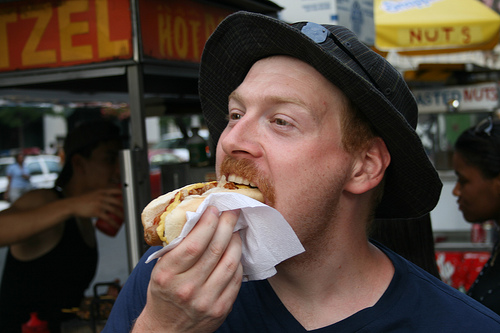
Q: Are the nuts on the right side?
A: Yes, the nuts are on the right of the image.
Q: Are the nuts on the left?
A: No, the nuts are on the right of the image.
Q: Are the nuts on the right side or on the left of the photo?
A: The nuts are on the right of the image.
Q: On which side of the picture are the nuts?
A: The nuts are on the right of the image.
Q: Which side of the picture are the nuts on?
A: The nuts are on the right of the image.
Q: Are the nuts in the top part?
A: Yes, the nuts are in the top of the image.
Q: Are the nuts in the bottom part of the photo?
A: No, the nuts are in the top of the image.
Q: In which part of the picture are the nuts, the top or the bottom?
A: The nuts are in the top of the image.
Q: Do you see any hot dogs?
A: Yes, there is a hot dog.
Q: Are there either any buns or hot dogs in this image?
A: Yes, there is a hot dog.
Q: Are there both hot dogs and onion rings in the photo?
A: No, there is a hot dog but no onion rings.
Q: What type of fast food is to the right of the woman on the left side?
A: The food is a hot dog.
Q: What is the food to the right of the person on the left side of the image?
A: The food is a hot dog.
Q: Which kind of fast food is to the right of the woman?
A: The food is a hot dog.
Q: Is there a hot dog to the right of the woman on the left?
A: Yes, there is a hot dog to the right of the woman.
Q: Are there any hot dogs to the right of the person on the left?
A: Yes, there is a hot dog to the right of the woman.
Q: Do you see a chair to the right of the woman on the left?
A: No, there is a hot dog to the right of the woman.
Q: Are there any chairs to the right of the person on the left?
A: No, there is a hot dog to the right of the woman.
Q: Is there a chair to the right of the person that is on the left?
A: No, there is a hot dog to the right of the woman.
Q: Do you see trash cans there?
A: No, there are no trash cans.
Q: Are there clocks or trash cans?
A: No, there are no trash cans or clocks.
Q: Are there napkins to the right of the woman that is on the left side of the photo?
A: Yes, there is a napkin to the right of the woman.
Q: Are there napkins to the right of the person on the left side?
A: Yes, there is a napkin to the right of the woman.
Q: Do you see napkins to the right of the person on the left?
A: Yes, there is a napkin to the right of the woman.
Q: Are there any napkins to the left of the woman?
A: No, the napkin is to the right of the woman.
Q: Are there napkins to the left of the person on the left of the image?
A: No, the napkin is to the right of the woman.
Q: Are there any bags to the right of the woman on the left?
A: No, there is a napkin to the right of the woman.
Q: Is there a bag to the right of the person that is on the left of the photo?
A: No, there is a napkin to the right of the woman.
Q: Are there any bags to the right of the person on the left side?
A: No, there is a napkin to the right of the woman.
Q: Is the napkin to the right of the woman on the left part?
A: Yes, the napkin is to the right of the woman.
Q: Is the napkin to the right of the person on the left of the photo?
A: Yes, the napkin is to the right of the woman.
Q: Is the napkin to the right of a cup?
A: No, the napkin is to the right of the woman.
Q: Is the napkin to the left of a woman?
A: No, the napkin is to the right of a woman.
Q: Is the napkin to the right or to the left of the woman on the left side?
A: The napkin is to the right of the woman.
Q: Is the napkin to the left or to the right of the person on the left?
A: The napkin is to the right of the woman.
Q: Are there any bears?
A: No, there are no bears.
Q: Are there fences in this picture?
A: No, there are no fences.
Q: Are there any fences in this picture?
A: No, there are no fences.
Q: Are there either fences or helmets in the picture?
A: No, there are no fences or helmets.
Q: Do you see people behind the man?
A: Yes, there is a person behind the man.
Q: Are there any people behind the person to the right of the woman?
A: Yes, there is a person behind the man.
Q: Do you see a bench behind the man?
A: No, there is a person behind the man.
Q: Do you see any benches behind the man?
A: No, there is a person behind the man.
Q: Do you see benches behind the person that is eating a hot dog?
A: No, there is a person behind the man.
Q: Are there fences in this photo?
A: No, there are no fences.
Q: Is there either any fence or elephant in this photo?
A: No, there are no fences or elephants.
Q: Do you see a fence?
A: No, there are no fences.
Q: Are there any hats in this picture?
A: Yes, there is a hat.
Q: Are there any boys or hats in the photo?
A: Yes, there is a hat.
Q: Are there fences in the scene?
A: No, there are no fences.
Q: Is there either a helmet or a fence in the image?
A: No, there are no fences or helmets.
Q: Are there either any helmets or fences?
A: No, there are no fences or helmets.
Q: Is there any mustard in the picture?
A: Yes, there is mustard.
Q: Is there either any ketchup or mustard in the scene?
A: Yes, there is mustard.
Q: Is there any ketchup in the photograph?
A: Yes, there is ketchup.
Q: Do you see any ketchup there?
A: Yes, there is ketchup.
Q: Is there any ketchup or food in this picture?
A: Yes, there is ketchup.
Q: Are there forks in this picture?
A: No, there are no forks.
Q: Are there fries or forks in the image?
A: No, there are no forks or fries.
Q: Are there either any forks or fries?
A: No, there are no forks or fries.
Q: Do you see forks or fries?
A: No, there are no forks or fries.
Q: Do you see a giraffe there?
A: No, there are no giraffes.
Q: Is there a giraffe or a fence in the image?
A: No, there are no giraffes or fences.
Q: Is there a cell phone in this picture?
A: No, there are no cell phones.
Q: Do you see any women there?
A: Yes, there is a woman.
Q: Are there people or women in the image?
A: Yes, there is a woman.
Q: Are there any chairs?
A: No, there are no chairs.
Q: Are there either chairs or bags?
A: No, there are no chairs or bags.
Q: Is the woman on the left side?
A: Yes, the woman is on the left of the image.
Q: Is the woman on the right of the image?
A: No, the woman is on the left of the image.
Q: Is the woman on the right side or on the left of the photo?
A: The woman is on the left of the image.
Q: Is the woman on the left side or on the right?
A: The woman is on the left of the image.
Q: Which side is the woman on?
A: The woman is on the left of the image.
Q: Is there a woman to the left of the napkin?
A: Yes, there is a woman to the left of the napkin.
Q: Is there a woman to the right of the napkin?
A: No, the woman is to the left of the napkin.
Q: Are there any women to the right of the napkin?
A: No, the woman is to the left of the napkin.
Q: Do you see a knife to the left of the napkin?
A: No, there is a woman to the left of the napkin.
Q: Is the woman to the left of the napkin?
A: Yes, the woman is to the left of the napkin.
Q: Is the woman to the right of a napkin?
A: No, the woman is to the left of a napkin.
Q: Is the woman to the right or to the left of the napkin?
A: The woman is to the left of the napkin.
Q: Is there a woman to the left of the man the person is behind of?
A: Yes, there is a woman to the left of the man.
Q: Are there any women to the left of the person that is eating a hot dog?
A: Yes, there is a woman to the left of the man.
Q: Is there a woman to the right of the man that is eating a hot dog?
A: No, the woman is to the left of the man.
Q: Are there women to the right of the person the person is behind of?
A: No, the woman is to the left of the man.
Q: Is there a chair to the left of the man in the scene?
A: No, there is a woman to the left of the man.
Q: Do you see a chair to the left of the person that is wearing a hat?
A: No, there is a woman to the left of the man.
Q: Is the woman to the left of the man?
A: Yes, the woman is to the left of the man.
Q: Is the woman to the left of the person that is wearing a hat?
A: Yes, the woman is to the left of the man.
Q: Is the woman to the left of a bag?
A: No, the woman is to the left of the man.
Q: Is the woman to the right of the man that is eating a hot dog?
A: No, the woman is to the left of the man.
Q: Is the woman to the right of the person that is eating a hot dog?
A: No, the woman is to the left of the man.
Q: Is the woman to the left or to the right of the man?
A: The woman is to the left of the man.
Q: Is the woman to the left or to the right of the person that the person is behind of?
A: The woman is to the left of the man.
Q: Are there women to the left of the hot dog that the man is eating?
A: Yes, there is a woman to the left of the hot dog.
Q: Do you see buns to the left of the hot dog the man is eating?
A: No, there is a woman to the left of the hot dog.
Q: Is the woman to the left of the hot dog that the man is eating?
A: Yes, the woman is to the left of the hot dog.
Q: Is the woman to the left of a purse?
A: No, the woman is to the left of the hot dog.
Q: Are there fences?
A: No, there are no fences.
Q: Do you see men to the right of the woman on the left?
A: Yes, there is a man to the right of the woman.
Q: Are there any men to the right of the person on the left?
A: Yes, there is a man to the right of the woman.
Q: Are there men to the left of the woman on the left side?
A: No, the man is to the right of the woman.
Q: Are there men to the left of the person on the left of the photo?
A: No, the man is to the right of the woman.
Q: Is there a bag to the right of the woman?
A: No, there is a man to the right of the woman.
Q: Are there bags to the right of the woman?
A: No, there is a man to the right of the woman.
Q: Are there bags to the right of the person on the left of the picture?
A: No, there is a man to the right of the woman.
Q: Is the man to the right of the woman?
A: Yes, the man is to the right of the woman.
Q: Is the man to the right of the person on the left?
A: Yes, the man is to the right of the woman.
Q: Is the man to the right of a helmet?
A: No, the man is to the right of the woman.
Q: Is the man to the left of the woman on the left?
A: No, the man is to the right of the woman.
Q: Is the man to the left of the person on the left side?
A: No, the man is to the right of the woman.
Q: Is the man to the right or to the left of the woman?
A: The man is to the right of the woman.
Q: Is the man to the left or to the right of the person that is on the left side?
A: The man is to the right of the woman.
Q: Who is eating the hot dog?
A: The man is eating the hot dog.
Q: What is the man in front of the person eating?
A: The man is eating a hot dog.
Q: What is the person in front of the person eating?
A: The man is eating a hot dog.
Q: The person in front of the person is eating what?
A: The man is eating a hot dog.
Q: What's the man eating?
A: The man is eating a hot dog.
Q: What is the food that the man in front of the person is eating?
A: The food is a hot dog.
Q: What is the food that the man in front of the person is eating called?
A: The food is a hot dog.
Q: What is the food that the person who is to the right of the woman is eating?
A: The food is a hot dog.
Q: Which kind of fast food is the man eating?
A: The man is eating a hot dog.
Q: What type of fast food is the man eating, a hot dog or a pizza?
A: The man is eating a hot dog.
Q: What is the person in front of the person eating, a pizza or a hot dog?
A: The man is eating a hot dog.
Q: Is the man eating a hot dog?
A: Yes, the man is eating a hot dog.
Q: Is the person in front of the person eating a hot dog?
A: Yes, the man is eating a hot dog.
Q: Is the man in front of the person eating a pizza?
A: No, the man is eating a hot dog.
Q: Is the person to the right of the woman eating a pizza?
A: No, the man is eating a hot dog.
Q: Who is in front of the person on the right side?
A: The man is in front of the person.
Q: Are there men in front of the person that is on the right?
A: Yes, there is a man in front of the person.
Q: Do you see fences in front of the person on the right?
A: No, there is a man in front of the person.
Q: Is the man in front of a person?
A: Yes, the man is in front of a person.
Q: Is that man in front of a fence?
A: No, the man is in front of a person.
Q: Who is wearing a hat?
A: The man is wearing a hat.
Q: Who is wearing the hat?
A: The man is wearing a hat.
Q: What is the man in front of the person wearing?
A: The man is wearing a hat.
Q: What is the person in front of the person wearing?
A: The man is wearing a hat.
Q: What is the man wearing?
A: The man is wearing a hat.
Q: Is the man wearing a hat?
A: Yes, the man is wearing a hat.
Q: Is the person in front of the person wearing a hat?
A: Yes, the man is wearing a hat.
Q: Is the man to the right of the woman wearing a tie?
A: No, the man is wearing a hat.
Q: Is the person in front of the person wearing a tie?
A: No, the man is wearing a hat.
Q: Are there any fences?
A: No, there are no fences.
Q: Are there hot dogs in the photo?
A: Yes, there is a hot dog.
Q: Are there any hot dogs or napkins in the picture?
A: Yes, there is a hot dog.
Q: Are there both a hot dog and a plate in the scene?
A: No, there is a hot dog but no plates.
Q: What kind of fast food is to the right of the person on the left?
A: The food is a hot dog.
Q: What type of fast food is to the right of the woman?
A: The food is a hot dog.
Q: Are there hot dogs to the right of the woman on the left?
A: Yes, there is a hot dog to the right of the woman.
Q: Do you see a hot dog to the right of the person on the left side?
A: Yes, there is a hot dog to the right of the woman.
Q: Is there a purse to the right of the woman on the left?
A: No, there is a hot dog to the right of the woman.